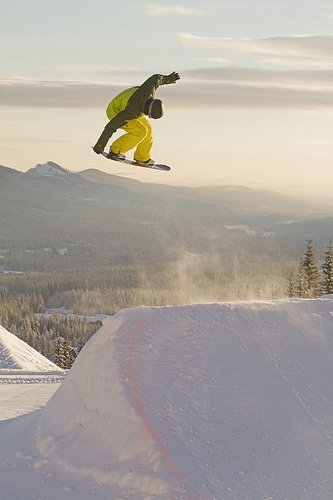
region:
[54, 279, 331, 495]
A jump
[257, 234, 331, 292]
Pine trees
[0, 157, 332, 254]
Mountains in the distance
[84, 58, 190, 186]
A snowboarder doing a jump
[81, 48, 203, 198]
The snowboarder is wearing yellow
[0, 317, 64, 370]
A ski slope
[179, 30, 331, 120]
It is partly cloudy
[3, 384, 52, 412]
packed snow on the ground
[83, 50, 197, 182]
the snow boarder is wearing a hat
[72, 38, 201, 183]
The snowboarder is wearing gloves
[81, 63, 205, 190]
an air born snowboarder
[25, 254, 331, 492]
a ramp made out of snow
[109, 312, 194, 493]
a red line in the snow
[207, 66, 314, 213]
clouds in the sky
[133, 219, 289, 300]
fog coming from the valley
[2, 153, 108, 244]
mountains in the background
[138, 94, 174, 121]
a brown helmet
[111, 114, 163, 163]
yellow ski pants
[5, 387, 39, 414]
snow covering the ground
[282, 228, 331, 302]
green pine trees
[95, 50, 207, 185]
man in the air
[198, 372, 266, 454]
white snow on the ground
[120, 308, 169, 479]
orange line on snow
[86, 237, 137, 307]
trees behind the snow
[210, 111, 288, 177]
bright sky in background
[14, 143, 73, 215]
hills in the background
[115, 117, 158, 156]
light pants of snowboarder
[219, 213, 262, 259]
water in the background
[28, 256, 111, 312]
many different trees in background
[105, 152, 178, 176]
feet of the man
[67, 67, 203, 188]
He is snow boarding.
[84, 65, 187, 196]
He is doing a trick.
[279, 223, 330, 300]
The trees are green.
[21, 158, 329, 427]
He is in the mountains.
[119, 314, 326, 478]
The ground is snow covered.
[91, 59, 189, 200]
He is wearing yellow pants.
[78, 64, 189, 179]
He is wearing gloves.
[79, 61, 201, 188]
He is wearing a brown helmet.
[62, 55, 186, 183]
He is holding his board.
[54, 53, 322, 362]
He is in the air.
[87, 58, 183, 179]
a man flying through the air on a snowboard.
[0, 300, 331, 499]
a ramp made of snow.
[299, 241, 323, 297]
a very tall green pine tree.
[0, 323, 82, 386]
a steep ski slope.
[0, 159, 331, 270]
and large snow and tree covered mountain range.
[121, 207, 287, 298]
mist coming off the snow.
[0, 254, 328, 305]
a forest covered in snow below a mountain.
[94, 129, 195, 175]
a snowboard above the snow.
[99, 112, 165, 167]
a pair of yellow pants.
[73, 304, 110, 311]
a section of snow covered forest.